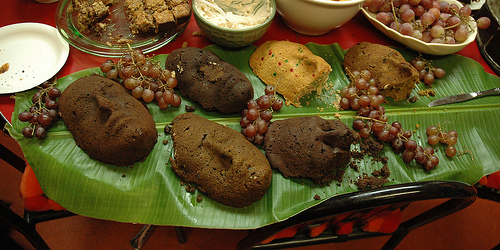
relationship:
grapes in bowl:
[364, 1, 494, 44] [359, 2, 486, 62]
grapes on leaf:
[13, 79, 68, 141] [6, 38, 500, 235]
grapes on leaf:
[96, 38, 185, 112] [6, 38, 500, 235]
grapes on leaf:
[231, 80, 287, 147] [6, 38, 500, 235]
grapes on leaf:
[334, 62, 391, 121] [6, 38, 500, 235]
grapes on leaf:
[351, 111, 440, 176] [6, 38, 500, 235]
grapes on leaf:
[424, 121, 465, 162] [6, 38, 500, 235]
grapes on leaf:
[409, 52, 449, 90] [6, 38, 500, 235]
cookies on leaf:
[164, 45, 266, 114] [6, 38, 500, 235]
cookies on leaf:
[260, 114, 358, 192] [6, 38, 500, 235]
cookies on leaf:
[247, 32, 337, 110] [6, 38, 500, 235]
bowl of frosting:
[188, 0, 286, 52] [195, 1, 273, 31]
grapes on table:
[13, 79, 68, 141] [3, 1, 500, 207]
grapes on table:
[96, 38, 185, 112] [3, 1, 500, 207]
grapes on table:
[231, 80, 287, 147] [3, 1, 500, 207]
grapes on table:
[334, 62, 391, 121] [3, 1, 500, 207]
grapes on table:
[351, 111, 440, 176] [3, 1, 500, 207]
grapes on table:
[409, 52, 449, 90] [3, 1, 500, 207]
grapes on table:
[424, 121, 465, 162] [3, 1, 500, 207]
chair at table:
[243, 167, 477, 250] [3, 1, 500, 207]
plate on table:
[1, 15, 75, 104] [3, 1, 500, 207]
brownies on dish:
[73, 2, 189, 38] [51, 1, 193, 63]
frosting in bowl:
[195, 1, 273, 31] [188, 0, 286, 52]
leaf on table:
[6, 38, 500, 235] [3, 1, 500, 207]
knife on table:
[424, 81, 500, 110] [3, 1, 500, 207]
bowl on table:
[188, 0, 286, 52] [3, 1, 500, 207]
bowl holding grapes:
[359, 2, 486, 62] [364, 1, 494, 44]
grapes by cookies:
[13, 79, 68, 141] [55, 68, 161, 173]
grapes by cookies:
[96, 38, 185, 112] [164, 45, 266, 114]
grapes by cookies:
[231, 80, 287, 147] [162, 107, 281, 210]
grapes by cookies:
[334, 62, 391, 121] [338, 34, 424, 107]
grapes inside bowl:
[364, 1, 494, 44] [359, 2, 486, 62]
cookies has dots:
[247, 32, 337, 110] [264, 47, 300, 79]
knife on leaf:
[424, 81, 500, 110] [6, 38, 500, 235]